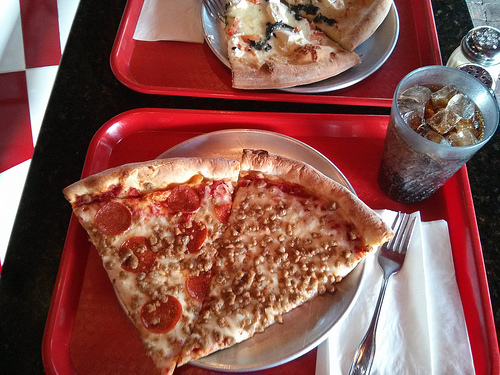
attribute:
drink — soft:
[376, 61, 500, 208]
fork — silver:
[351, 211, 417, 374]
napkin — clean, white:
[315, 207, 482, 373]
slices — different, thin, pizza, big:
[62, 146, 398, 374]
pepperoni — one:
[93, 204, 135, 236]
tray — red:
[110, 1, 446, 110]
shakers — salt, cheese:
[446, 25, 499, 97]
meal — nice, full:
[52, 66, 496, 374]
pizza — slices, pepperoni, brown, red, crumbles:
[62, 156, 242, 374]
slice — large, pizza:
[174, 142, 395, 374]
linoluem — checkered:
[2, 2, 82, 302]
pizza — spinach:
[224, 1, 396, 92]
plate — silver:
[135, 125, 368, 373]